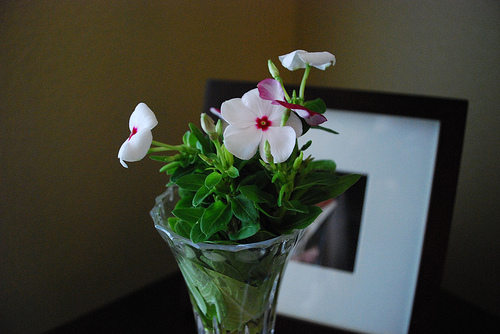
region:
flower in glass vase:
[218, 75, 303, 170]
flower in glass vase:
[278, 36, 335, 81]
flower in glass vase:
[101, 90, 172, 178]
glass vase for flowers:
[131, 183, 357, 332]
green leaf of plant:
[291, 193, 322, 237]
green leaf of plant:
[313, 170, 374, 212]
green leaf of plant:
[196, 168, 221, 208]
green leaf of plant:
[199, 200, 228, 238]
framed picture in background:
[211, 66, 449, 318]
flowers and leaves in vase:
[101, 8, 366, 331]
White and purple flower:
[114, 98, 161, 170]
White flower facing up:
[281, 47, 333, 71]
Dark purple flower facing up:
[253, 75, 327, 127]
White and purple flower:
[217, 86, 304, 165]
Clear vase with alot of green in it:
[151, 184, 295, 331]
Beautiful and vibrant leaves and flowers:
[115, 49, 358, 329]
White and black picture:
[197, 70, 465, 332]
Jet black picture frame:
[193, 76, 468, 332]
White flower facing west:
[116, 100, 158, 172]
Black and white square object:
[202, 73, 475, 333]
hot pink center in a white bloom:
[257, 111, 271, 133]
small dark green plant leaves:
[181, 168, 254, 220]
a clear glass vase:
[154, 200, 318, 313]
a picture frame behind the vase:
[181, 82, 432, 332]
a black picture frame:
[198, 85, 466, 123]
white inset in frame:
[337, 120, 408, 322]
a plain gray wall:
[9, 9, 194, 283]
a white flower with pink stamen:
[224, 87, 294, 164]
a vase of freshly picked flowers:
[105, 6, 394, 319]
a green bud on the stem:
[192, 105, 214, 136]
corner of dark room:
[1, 1, 496, 330]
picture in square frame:
[199, 76, 469, 331]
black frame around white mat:
[197, 79, 469, 331]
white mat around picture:
[278, 109, 437, 331]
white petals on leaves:
[223, 86, 293, 164]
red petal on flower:
[274, 98, 309, 115]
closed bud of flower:
[199, 111, 217, 139]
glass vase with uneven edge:
[151, 187, 306, 332]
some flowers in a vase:
[116, 27, 341, 324]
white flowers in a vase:
[119, 50, 356, 332]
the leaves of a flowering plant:
[179, 163, 230, 219]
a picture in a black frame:
[196, 67, 471, 332]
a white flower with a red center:
[115, 102, 155, 165]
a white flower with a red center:
[220, 85, 298, 160]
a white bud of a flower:
[196, 107, 221, 139]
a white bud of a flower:
[265, 51, 281, 82]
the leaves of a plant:
[289, 160, 344, 199]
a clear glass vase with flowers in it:
[116, 44, 346, 327]